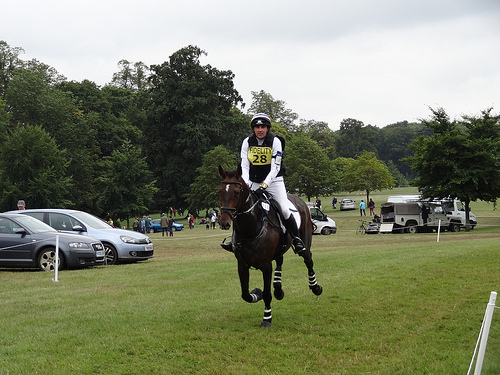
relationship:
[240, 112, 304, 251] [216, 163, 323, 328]
man riding horse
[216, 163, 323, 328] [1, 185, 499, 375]
horse running in field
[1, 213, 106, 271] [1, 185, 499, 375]
car parked in field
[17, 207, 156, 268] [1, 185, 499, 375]
car parked in field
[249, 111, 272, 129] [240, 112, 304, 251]
helmet on man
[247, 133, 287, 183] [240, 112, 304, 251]
vest on man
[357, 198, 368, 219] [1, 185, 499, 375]
person standing in field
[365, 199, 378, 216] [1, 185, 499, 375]
person standing in field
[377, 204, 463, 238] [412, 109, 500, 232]
truck parked under tree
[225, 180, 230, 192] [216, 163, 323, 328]
spot on horse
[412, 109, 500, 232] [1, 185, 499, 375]
tree growing out of field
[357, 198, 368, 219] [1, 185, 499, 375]
person walking in field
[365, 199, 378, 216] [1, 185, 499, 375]
person walking in field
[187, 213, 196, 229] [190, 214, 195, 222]
person wearing a red shirt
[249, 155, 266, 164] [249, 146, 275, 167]
number on sign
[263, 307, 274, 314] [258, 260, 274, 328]
stripe on leg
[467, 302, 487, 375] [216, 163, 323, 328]
fence beside horse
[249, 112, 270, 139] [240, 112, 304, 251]
head of man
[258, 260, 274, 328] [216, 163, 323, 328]
leg of horse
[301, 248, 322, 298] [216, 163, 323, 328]
leg of horse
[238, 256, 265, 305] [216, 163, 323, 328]
leg of horse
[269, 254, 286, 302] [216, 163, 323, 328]
leg of horse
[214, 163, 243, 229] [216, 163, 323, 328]
head of horse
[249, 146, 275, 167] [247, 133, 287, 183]
sign on vest